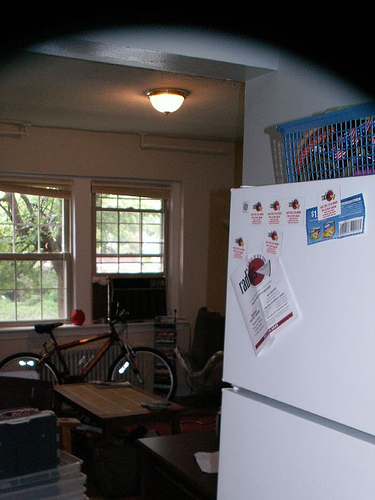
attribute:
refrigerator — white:
[208, 174, 373, 498]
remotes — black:
[141, 397, 176, 414]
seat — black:
[18, 309, 62, 335]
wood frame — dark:
[57, 373, 187, 430]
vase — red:
[62, 304, 92, 325]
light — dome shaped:
[143, 86, 191, 113]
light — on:
[143, 88, 192, 116]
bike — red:
[1, 309, 176, 400]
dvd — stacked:
[146, 315, 178, 366]